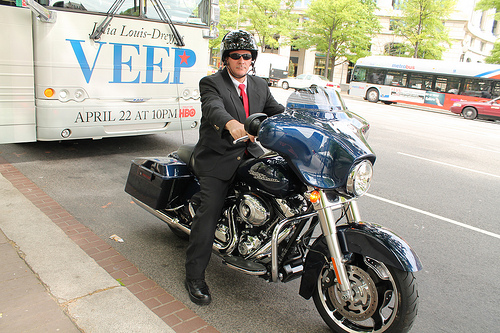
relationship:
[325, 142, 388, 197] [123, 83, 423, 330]
headlight of motorcycle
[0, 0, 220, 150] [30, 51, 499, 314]
bus on street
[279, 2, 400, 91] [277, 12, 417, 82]
leaves growing on tree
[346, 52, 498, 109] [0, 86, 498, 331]
bus bus side on street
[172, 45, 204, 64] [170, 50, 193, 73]
star next to star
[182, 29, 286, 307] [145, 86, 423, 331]
man sitting on motor bike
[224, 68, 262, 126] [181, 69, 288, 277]
tie on suit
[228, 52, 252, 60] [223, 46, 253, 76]
glasses on face of face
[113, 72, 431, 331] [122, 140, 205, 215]
motorcycle has storage bin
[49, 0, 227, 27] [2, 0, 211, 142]
windshield of bus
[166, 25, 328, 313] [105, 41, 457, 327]
man riding motorcycle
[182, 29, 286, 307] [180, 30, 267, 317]
man wearing suit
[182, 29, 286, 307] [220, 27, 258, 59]
man wearing helmet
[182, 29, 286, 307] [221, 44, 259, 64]
man wearing sunglasses